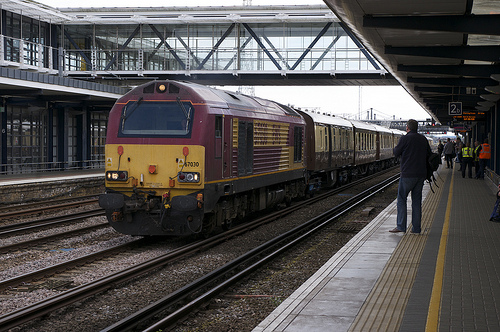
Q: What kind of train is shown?
A: Passengers' train.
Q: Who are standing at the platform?
A: Passengers.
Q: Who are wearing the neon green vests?
A: Officers.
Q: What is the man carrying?
A: A bag.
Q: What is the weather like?
A: Gloomy.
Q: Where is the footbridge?
A: On top of the train.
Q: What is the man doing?
A: Standing.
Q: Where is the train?
A: At the train tracks.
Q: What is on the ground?
A: A yellow line.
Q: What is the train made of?
A: Metal and steel.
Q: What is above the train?
A: A bridge connecting one side of the platform to another.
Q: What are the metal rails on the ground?
A: Train tracks.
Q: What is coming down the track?
A: Train.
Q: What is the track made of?
A: Metal.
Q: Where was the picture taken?
A: Train station.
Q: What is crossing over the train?
A: Pedway.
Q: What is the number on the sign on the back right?
A: 2.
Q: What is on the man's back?
A: Backpack.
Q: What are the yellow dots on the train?
A: Light.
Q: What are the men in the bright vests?
A: Security.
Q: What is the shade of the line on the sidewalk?
A: Yellow.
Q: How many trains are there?
A: One.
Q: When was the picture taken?
A: Daytime.